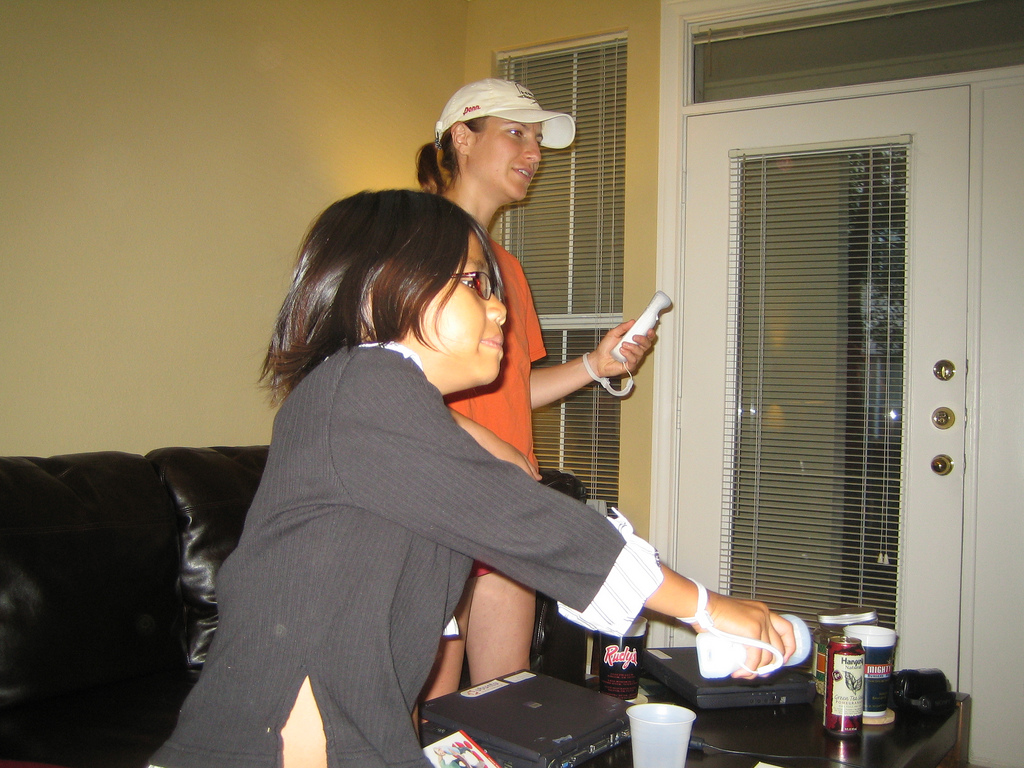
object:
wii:
[610, 288, 675, 367]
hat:
[429, 76, 578, 154]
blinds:
[720, 143, 917, 687]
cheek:
[400, 289, 487, 381]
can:
[821, 632, 870, 741]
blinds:
[483, 30, 631, 519]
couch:
[0, 437, 592, 765]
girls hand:
[695, 585, 794, 677]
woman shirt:
[440, 224, 549, 482]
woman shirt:
[143, 334, 664, 766]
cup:
[622, 696, 695, 767]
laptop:
[632, 640, 808, 710]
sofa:
[0, 442, 589, 763]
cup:
[591, 617, 651, 702]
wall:
[2, 0, 661, 552]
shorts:
[476, 558, 498, 578]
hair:
[253, 186, 505, 409]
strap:
[682, 560, 813, 688]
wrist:
[676, 571, 724, 633]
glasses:
[438, 267, 506, 303]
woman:
[408, 72, 659, 702]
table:
[409, 638, 976, 766]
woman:
[138, 186, 797, 764]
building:
[0, 0, 1024, 768]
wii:
[691, 606, 817, 685]